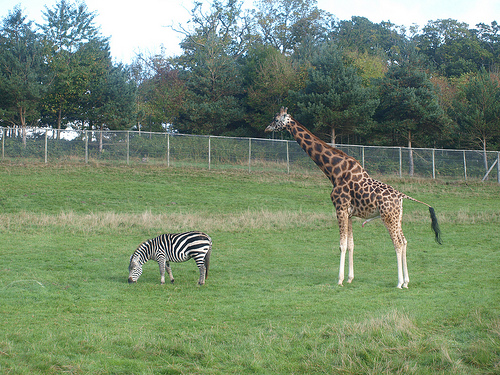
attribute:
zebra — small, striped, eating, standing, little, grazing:
[127, 230, 213, 285]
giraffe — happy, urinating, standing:
[263, 106, 443, 289]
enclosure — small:
[0, 127, 499, 373]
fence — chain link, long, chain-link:
[1, 125, 500, 180]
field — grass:
[1, 163, 500, 373]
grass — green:
[2, 159, 499, 371]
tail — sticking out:
[402, 192, 445, 243]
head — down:
[126, 257, 144, 283]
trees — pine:
[0, 0, 499, 169]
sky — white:
[1, 1, 499, 73]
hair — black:
[426, 205, 444, 244]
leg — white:
[336, 212, 347, 287]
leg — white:
[346, 219, 354, 282]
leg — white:
[387, 223, 402, 289]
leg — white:
[399, 223, 410, 288]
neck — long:
[289, 118, 352, 182]